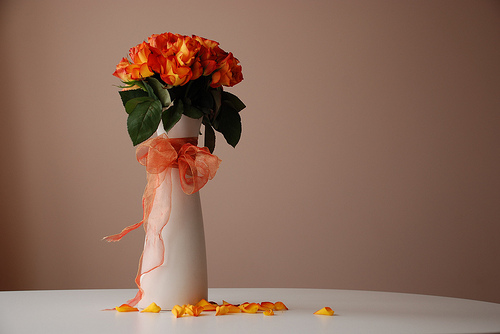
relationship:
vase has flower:
[133, 108, 209, 314] [206, 50, 244, 90]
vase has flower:
[133, 108, 209, 314] [223, 55, 242, 85]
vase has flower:
[133, 108, 209, 314] [114, 57, 134, 80]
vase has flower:
[133, 108, 209, 314] [154, 35, 182, 52]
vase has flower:
[133, 108, 209, 314] [183, 35, 200, 60]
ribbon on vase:
[104, 136, 222, 310] [133, 108, 209, 314]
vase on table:
[133, 108, 209, 314] [0, 289, 500, 333]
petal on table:
[310, 305, 335, 315] [0, 289, 500, 333]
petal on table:
[116, 305, 140, 312] [0, 289, 500, 333]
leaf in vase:
[127, 99, 161, 144] [133, 108, 209, 314]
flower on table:
[206, 50, 244, 90] [0, 289, 500, 333]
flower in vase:
[206, 50, 244, 90] [133, 108, 209, 314]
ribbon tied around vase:
[104, 136, 222, 310] [133, 108, 209, 314]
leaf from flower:
[127, 99, 161, 144] [206, 50, 244, 90]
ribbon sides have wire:
[104, 136, 222, 310] [131, 265, 163, 283]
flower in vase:
[154, 35, 182, 52] [133, 108, 209, 314]